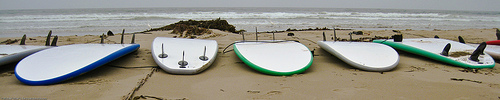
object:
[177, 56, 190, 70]
mark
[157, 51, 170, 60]
mark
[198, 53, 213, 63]
mark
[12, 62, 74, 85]
edge of board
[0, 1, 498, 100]
part of beach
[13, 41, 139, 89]
surface of board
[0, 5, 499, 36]
part of water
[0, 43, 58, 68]
surfboards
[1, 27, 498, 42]
edge of shore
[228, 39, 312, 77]
surfboard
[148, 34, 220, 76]
bottom of board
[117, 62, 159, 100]
cable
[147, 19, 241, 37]
rock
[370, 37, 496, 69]
surfboard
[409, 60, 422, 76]
line